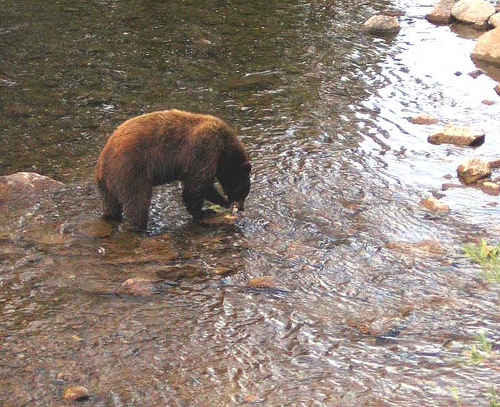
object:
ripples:
[250, 55, 414, 338]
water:
[3, 5, 499, 397]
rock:
[359, 8, 403, 39]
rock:
[448, 1, 496, 29]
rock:
[466, 28, 499, 67]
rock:
[403, 110, 441, 128]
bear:
[93, 105, 255, 233]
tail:
[95, 158, 107, 188]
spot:
[437, 323, 447, 330]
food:
[229, 207, 247, 220]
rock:
[425, 129, 485, 149]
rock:
[0, 167, 68, 192]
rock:
[422, 3, 458, 27]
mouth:
[229, 198, 244, 218]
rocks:
[114, 277, 153, 295]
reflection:
[153, 218, 249, 293]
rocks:
[425, 126, 488, 149]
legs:
[108, 165, 150, 230]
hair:
[228, 146, 246, 161]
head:
[216, 161, 254, 213]